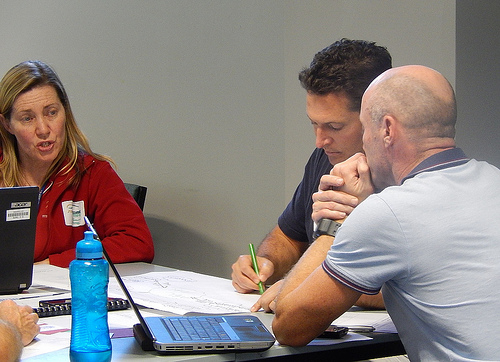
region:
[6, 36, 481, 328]
people working at a table together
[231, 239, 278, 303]
man holding green metallic pen in right hand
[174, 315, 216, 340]
keys on the computer keyboard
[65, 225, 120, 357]
see through blue plastic water bottle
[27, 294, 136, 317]
spiral side of binder full of paper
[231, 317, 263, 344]
touch pad on the laptop computer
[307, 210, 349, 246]
black plastic watch on the man's wrist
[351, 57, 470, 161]
man has lost a lot of hair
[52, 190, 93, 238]
name tag sticker on red sweatshirt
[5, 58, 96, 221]
woman with long blonde straight hair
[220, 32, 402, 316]
a man sitting at a table.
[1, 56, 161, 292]
a woman in a red shirt.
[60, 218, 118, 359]
a blue water bottle.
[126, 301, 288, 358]
a device on a table.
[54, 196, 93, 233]
name tag on a shirt,.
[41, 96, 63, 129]
a left human eye.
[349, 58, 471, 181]
a blad headed man.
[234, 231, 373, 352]
a left human arm.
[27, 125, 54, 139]
a nose on a woman.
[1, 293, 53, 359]
an arm on a table.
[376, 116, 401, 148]
the man's left ear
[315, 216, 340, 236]
watch on man's arm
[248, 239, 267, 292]
green pen in man's hand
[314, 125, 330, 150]
nose on the man's face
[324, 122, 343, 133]
the man's left eye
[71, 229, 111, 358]
blue water on the table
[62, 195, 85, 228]
white tag on woman's shirt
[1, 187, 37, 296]
black laptop on desk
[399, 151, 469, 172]
collar on the man's shirt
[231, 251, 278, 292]
the man's right hand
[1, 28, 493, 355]
several people converse over computers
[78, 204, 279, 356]
someone's laptop being used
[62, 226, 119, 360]
a sport bottle of water is nearly empty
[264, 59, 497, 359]
one of the discussion members is bald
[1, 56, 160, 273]
this discussion member wears a red jacket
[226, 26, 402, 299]
this discussion member is taking notes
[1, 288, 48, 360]
a fourth discussion member can barely be seen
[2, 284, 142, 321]
a spiral notebook on the table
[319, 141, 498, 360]
the bald guy is wearing a polo shirt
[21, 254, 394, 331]
a paper graph is the subject of discussion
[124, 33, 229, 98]
The wall is smooth.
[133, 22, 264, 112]
The wall is white in color.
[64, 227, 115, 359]
The water bottle is on the table.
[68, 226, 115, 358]
The water bottle is blue.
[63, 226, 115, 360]
The water bottle is made of plastic.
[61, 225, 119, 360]
The water bottle has very little liquid inside.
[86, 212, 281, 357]
The laptop is open.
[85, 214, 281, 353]
The laptop is on the desk.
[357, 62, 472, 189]
The man is balding.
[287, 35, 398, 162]
The man has brown hair.